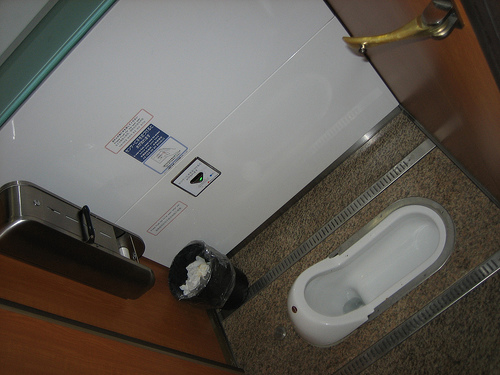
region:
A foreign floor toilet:
[258, 198, 452, 324]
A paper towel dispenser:
[5, 172, 149, 274]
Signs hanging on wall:
[91, 113, 226, 186]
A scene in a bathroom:
[59, 73, 459, 346]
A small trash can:
[162, 244, 263, 314]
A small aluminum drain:
[293, 220, 350, 240]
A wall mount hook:
[332, 21, 474, 63]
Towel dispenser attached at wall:
[13, 173, 150, 289]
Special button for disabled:
[177, 166, 224, 205]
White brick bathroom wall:
[197, 41, 298, 136]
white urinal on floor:
[262, 200, 480, 337]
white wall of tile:
[46, 3, 408, 268]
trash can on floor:
[155, 240, 276, 328]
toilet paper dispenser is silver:
[6, 181, 201, 275]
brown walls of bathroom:
[1, 257, 236, 322]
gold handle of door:
[335, 9, 480, 71]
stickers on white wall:
[95, 100, 266, 225]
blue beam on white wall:
[0, 11, 114, 91]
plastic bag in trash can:
[164, 248, 242, 308]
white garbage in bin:
[167, 271, 264, 311]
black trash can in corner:
[147, 232, 264, 317]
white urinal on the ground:
[269, 199, 481, 351]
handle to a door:
[312, 1, 481, 62]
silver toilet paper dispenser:
[8, 169, 163, 314]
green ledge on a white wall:
[2, 0, 122, 115]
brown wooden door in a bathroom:
[380, 54, 494, 151]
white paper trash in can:
[173, 257, 214, 293]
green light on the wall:
[172, 160, 218, 195]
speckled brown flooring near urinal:
[414, 315, 498, 365]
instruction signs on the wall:
[92, 102, 205, 179]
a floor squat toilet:
[272, 192, 451, 350]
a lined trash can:
[163, 238, 247, 317]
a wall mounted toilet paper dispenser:
[2, 179, 153, 300]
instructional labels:
[99, 105, 190, 182]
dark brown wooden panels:
[3, 240, 235, 372]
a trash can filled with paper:
[163, 237, 250, 317]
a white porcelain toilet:
[278, 196, 449, 353]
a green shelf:
[1, 2, 106, 137]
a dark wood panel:
[330, 4, 495, 213]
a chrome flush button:
[270, 322, 286, 344]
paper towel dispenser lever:
[71, 197, 97, 244]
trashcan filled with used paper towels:
[163, 235, 249, 311]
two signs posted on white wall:
[96, 102, 186, 172]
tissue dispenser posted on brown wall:
[0, 177, 155, 297]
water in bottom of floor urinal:
[322, 260, 362, 321]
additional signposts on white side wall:
[143, 159, 228, 236]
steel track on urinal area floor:
[360, 156, 407, 191]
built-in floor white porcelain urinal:
[285, 200, 455, 355]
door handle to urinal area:
[340, 0, 460, 41]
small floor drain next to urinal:
[267, 313, 292, 349]